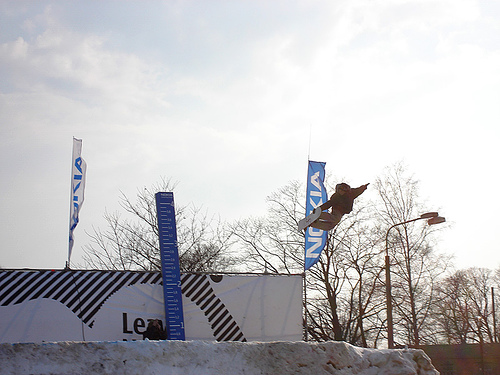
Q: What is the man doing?
A: Snowboarding.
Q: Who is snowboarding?
A: A Man.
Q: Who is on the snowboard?
A: A man.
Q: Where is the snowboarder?
A: In air.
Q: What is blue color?
A: Ruler.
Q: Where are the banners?
A: On poles.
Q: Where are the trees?
A: In distance.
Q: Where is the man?
A: On snowboard.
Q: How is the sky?
A: Cloudy.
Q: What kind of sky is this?
A: This is a white sky.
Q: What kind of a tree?
A: The tree has brown color.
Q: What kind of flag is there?
A: That is a blue flag.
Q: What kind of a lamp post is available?
A: A brown color.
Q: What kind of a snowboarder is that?
A: The snowboarder is very athletic.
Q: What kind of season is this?
A: Winter.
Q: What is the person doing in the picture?
A: Snowboarding.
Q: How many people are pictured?
A: One.